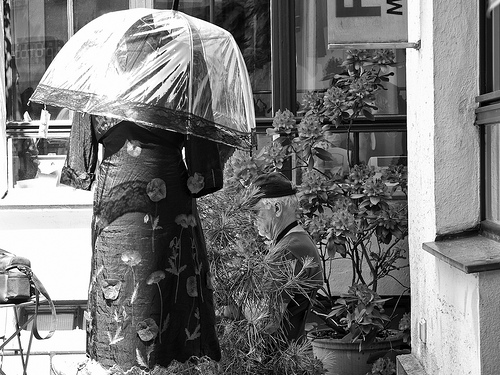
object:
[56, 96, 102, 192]
sleeve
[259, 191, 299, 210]
hair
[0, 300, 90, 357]
table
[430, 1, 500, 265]
window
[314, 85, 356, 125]
flower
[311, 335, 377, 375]
large pot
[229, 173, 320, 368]
man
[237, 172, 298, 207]
cap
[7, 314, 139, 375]
ground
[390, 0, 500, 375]
wall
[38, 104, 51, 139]
tag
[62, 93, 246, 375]
dress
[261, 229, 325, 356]
shirt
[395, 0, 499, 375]
building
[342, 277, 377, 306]
flowers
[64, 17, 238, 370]
person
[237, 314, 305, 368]
step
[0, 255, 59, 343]
bag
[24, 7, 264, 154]
canopy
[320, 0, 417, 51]
sign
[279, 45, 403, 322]
plant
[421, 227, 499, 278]
ledge